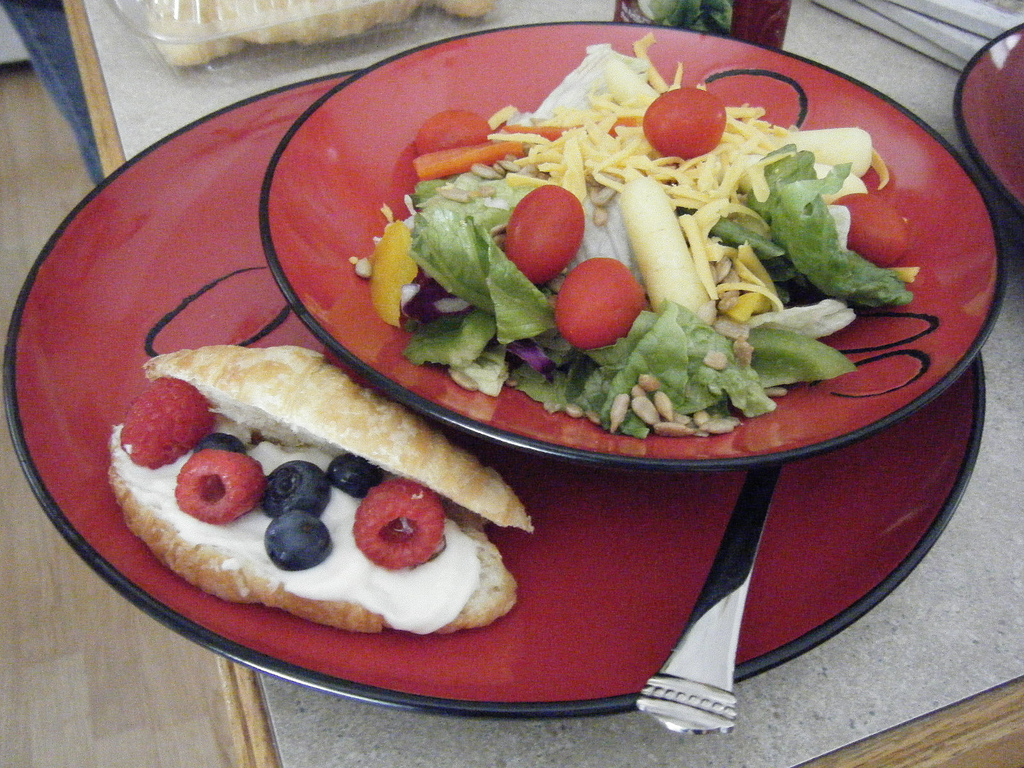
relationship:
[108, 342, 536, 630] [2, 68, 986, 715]
croissant on plate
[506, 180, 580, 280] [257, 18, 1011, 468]
tomato on plate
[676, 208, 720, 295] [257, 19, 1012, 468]
cheese on plate